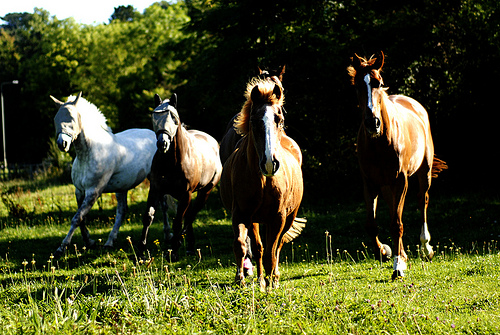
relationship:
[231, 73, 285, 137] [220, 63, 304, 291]
mane on horse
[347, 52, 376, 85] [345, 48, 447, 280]
mane on horse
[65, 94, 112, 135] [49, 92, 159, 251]
mane on horse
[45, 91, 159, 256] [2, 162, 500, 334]
horse on grass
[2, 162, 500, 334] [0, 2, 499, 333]
grass in field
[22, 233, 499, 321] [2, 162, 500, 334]
flowers on grass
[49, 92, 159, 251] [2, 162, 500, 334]
horse on grass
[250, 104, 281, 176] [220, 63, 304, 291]
face on horse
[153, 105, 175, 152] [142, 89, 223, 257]
face on horse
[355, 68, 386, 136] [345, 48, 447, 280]
face on horse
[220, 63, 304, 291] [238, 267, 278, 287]
horse has hooves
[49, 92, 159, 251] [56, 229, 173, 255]
horse has hooves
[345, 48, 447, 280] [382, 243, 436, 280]
horse has hooves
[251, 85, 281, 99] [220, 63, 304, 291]
ears on horse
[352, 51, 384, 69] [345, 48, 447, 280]
ears on horse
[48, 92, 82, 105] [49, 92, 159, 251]
ears on horse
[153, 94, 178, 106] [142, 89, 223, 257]
ears on horse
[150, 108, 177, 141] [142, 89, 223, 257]
mask on horse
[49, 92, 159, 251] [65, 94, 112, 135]
horse has a mane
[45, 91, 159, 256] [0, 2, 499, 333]
horse in field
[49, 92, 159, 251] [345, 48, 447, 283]
horse running with horse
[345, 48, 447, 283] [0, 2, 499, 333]
horse running in field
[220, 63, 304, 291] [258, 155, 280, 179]
horse has a nose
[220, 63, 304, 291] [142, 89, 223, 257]
horse in front of o horse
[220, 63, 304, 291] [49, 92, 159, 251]
horse in front of o horse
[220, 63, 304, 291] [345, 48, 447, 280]
horse in front of o horse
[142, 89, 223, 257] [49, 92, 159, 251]
horse beside horse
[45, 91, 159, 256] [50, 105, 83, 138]
horse wearing mask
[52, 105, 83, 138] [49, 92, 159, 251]
mask on horse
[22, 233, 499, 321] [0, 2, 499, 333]
flowers on field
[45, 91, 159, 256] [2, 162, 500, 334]
horse running in grass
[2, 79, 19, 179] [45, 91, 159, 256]
streetlight behind horse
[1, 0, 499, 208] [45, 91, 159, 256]
trees behind horse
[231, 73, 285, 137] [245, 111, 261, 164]
mane on neck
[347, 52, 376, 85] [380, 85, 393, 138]
mane on neck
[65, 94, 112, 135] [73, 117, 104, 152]
mane on neck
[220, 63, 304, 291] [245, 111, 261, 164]
horse has a neck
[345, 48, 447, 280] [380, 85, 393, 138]
horse has a neck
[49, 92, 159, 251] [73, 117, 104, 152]
horse has a neck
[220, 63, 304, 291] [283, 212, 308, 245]
horse has a tail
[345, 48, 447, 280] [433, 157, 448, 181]
horse has a tail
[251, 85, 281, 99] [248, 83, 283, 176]
ears on head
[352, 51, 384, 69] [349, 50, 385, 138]
ears on head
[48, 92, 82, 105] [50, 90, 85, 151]
ears on head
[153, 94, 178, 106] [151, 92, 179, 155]
ears on head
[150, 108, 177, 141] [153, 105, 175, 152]
mask on face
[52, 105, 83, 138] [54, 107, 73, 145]
mask on face